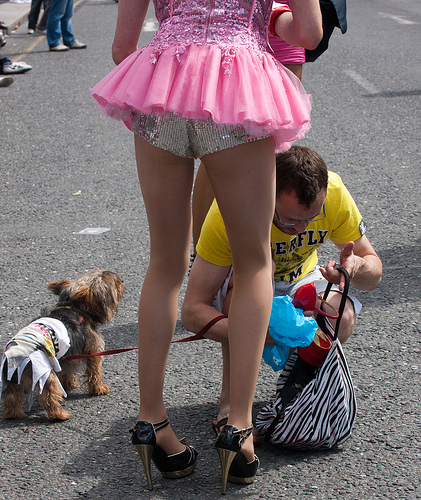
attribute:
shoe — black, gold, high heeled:
[211, 423, 260, 494]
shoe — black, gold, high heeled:
[130, 415, 202, 487]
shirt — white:
[0, 314, 71, 394]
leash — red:
[60, 314, 229, 362]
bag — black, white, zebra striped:
[253, 264, 358, 453]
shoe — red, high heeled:
[293, 280, 339, 360]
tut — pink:
[85, 49, 300, 130]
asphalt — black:
[29, 197, 54, 232]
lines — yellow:
[3, 44, 54, 79]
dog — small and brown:
[4, 259, 111, 422]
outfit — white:
[7, 316, 57, 387]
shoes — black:
[113, 454, 243, 497]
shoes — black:
[99, 398, 265, 482]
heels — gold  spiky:
[137, 458, 235, 492]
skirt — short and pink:
[128, 83, 260, 118]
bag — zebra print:
[256, 323, 362, 450]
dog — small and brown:
[0, 242, 112, 443]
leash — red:
[99, 334, 131, 369]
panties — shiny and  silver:
[145, 101, 215, 140]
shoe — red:
[278, 285, 338, 353]